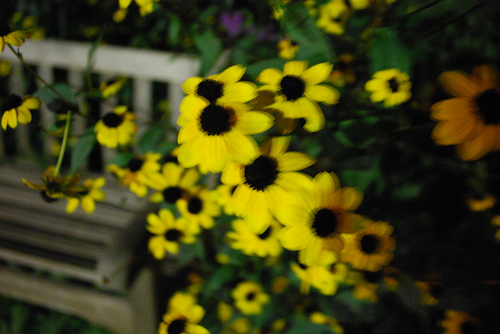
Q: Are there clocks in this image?
A: No, there are no clocks.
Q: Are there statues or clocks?
A: No, there are no clocks or statues.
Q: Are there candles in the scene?
A: No, there are no candles.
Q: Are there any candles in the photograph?
A: No, there are no candles.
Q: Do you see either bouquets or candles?
A: No, there are no candles or bouquets.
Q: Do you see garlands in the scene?
A: No, there are no garlands.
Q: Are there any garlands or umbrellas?
A: No, there are no garlands or umbrellas.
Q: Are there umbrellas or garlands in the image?
A: No, there are no garlands or umbrellas.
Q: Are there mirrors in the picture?
A: No, there are no mirrors.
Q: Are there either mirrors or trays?
A: No, there are no mirrors or trays.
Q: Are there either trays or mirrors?
A: No, there are no mirrors or trays.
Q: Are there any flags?
A: No, there are no flags.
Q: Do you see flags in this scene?
A: No, there are no flags.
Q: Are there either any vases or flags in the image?
A: No, there are no flags or vases.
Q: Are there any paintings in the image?
A: No, there are no paintings.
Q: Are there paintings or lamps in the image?
A: No, there are no paintings or lamps.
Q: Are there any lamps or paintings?
A: No, there are no paintings or lamps.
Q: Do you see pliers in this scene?
A: No, there are no pliers.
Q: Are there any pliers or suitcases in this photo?
A: No, there are no pliers or suitcases.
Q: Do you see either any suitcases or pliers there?
A: No, there are no pliers or suitcases.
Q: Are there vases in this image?
A: No, there are no vases.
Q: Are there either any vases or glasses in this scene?
A: No, there are no vases or glasses.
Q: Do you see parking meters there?
A: No, there are no parking meters.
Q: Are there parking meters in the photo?
A: No, there are no parking meters.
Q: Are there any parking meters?
A: No, there are no parking meters.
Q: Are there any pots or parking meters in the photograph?
A: No, there are no parking meters or pots.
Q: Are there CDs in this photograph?
A: No, there are no cds.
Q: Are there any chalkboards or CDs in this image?
A: No, there are no CDs or chalkboards.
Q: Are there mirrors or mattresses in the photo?
A: No, there are no mirrors or mattresses.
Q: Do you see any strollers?
A: No, there are no strollers.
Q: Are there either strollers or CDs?
A: No, there are no strollers or cds.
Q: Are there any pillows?
A: No, there are no pillows.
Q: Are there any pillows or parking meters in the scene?
A: No, there are no pillows or parking meters.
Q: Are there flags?
A: No, there are no flags.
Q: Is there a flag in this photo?
A: No, there are no flags.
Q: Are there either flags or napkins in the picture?
A: No, there are no flags or napkins.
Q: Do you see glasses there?
A: No, there are no glasses.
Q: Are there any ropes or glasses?
A: No, there are no glasses or ropes.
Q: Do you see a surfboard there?
A: No, there are no surfboards.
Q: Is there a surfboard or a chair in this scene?
A: No, there are no surfboards or chairs.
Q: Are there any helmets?
A: No, there are no helmets.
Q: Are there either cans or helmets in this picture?
A: No, there are no helmets or cans.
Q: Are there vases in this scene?
A: No, there are no vases.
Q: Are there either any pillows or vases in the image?
A: No, there are no vases or pillows.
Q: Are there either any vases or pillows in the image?
A: No, there are no vases or pillows.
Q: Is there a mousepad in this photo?
A: No, there are no mouse pads.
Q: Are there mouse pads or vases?
A: No, there are no mouse pads or vases.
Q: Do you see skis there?
A: No, there are no skis.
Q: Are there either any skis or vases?
A: No, there are no skis or vases.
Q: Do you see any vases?
A: No, there are no vases.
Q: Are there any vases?
A: No, there are no vases.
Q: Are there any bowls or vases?
A: No, there are no vases or bowls.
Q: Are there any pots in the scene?
A: No, there are no pots.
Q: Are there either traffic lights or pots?
A: No, there are no pots or traffic lights.